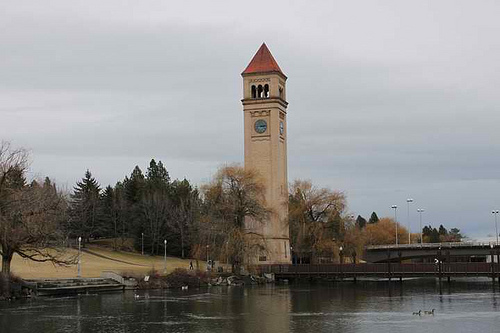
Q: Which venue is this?
A: This is a park.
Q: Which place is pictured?
A: It is a park.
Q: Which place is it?
A: It is a park.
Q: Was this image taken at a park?
A: Yes, it was taken in a park.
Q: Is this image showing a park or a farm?
A: It is showing a park.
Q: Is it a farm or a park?
A: It is a park.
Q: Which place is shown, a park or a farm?
A: It is a park.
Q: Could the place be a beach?
A: No, it is a park.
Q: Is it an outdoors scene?
A: Yes, it is outdoors.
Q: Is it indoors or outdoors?
A: It is outdoors.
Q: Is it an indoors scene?
A: No, it is outdoors.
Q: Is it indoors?
A: No, it is outdoors.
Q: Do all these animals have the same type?
A: Yes, all the animals are ducks.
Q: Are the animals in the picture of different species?
A: No, all the animals are ducks.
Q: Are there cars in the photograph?
A: No, there are no cars.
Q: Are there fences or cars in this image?
A: No, there are no cars or fences.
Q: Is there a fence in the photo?
A: No, there are no fences.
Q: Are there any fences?
A: No, there are no fences.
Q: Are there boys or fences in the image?
A: No, there are no fences or boys.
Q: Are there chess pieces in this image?
A: No, there are no chess pieces.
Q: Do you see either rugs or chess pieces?
A: No, there are no chess pieces or rugs.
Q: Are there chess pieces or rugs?
A: No, there are no chess pieces or rugs.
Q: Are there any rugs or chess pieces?
A: No, there are no chess pieces or rugs.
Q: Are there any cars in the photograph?
A: No, there are no cars.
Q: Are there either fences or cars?
A: No, there are no cars or fences.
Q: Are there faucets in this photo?
A: No, there are no faucets.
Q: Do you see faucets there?
A: No, there are no faucets.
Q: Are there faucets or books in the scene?
A: No, there are no faucets or books.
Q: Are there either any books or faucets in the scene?
A: No, there are no faucets or books.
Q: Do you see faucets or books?
A: No, there are no faucets or books.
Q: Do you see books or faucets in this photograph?
A: No, there are no faucets or books.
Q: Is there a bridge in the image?
A: Yes, there is a bridge.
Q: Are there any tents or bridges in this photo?
A: Yes, there is a bridge.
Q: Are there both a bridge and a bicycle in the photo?
A: No, there is a bridge but no bicycles.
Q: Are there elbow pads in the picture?
A: No, there are no elbow pads.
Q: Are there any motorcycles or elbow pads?
A: No, there are no elbow pads or motorcycles.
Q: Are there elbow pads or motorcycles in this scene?
A: No, there are no elbow pads or motorcycles.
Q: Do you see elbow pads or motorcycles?
A: No, there are no elbow pads or motorcycles.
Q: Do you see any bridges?
A: Yes, there is a bridge.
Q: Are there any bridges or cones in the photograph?
A: Yes, there is a bridge.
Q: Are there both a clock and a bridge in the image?
A: Yes, there are both a bridge and a clock.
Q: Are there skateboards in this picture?
A: No, there are no skateboards.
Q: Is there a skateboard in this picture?
A: No, there are no skateboards.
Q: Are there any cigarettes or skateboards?
A: No, there are no skateboards or cigarettes.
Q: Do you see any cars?
A: No, there are no cars.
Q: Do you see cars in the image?
A: No, there are no cars.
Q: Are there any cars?
A: No, there are no cars.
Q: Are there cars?
A: No, there are no cars.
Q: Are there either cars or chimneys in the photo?
A: No, there are no cars or chimneys.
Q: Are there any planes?
A: No, there are no planes.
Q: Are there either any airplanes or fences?
A: No, there are no airplanes or fences.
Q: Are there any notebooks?
A: No, there are no notebooks.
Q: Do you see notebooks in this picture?
A: No, there are no notebooks.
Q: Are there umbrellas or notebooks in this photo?
A: No, there are no notebooks or umbrellas.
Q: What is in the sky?
A: The clouds are in the sky.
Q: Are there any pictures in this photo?
A: No, there are no pictures.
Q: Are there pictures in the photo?
A: No, there are no pictures.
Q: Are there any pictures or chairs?
A: No, there are no pictures or chairs.